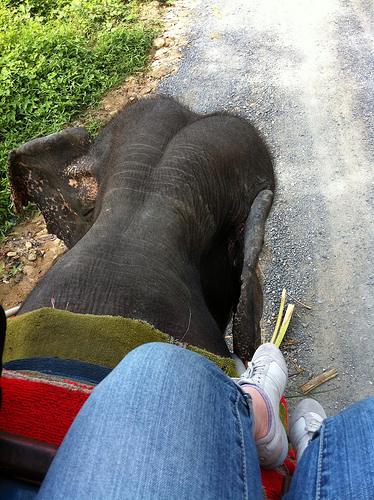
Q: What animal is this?
A: Elephant.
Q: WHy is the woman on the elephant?
A: To ride.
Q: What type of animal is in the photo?
A: Elephant.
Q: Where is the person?
A: Sitting on top of the elephant.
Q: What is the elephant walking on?
A: Road.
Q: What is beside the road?
A: Bushes.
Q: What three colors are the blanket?
A: Green, blue and red.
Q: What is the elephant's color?
A: Grey.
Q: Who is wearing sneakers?
A: Person on elephant.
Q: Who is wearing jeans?
A: Person on elephant.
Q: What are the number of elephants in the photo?
A: 1.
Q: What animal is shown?
A: Elephant.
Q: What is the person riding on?
A: Elephant.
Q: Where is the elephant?
A: Road.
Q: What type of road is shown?
A: Paved.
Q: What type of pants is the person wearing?
A: Jeans.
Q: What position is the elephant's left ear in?
A: Out.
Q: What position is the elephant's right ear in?
A: Laid back.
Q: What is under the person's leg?
A: Blanket.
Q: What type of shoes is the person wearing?
A: Tennis shoes.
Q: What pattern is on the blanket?
A: Stripes.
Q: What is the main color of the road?
A: Gray.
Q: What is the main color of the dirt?
A: Brown.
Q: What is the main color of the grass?
A: Green.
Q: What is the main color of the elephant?
A: Gray.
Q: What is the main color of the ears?
A: Grey.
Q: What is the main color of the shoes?
A: White.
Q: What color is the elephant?
A: Dark gray.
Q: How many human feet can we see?
A: Two.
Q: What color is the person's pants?
A: Blue.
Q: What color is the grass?
A: Green.